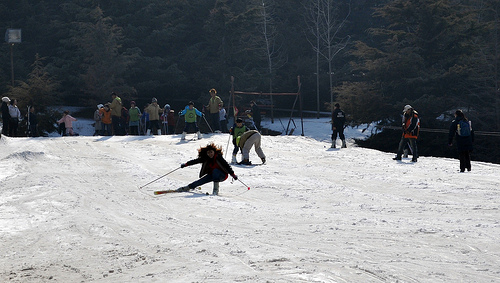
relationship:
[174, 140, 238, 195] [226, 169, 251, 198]
person on skis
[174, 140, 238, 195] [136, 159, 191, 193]
person on skis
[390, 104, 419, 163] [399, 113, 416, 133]
man wearing jacket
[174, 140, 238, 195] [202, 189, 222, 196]
person on ski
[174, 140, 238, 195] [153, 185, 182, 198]
person on ski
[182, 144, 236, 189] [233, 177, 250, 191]
person holding pole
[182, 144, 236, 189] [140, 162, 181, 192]
person holding ski pole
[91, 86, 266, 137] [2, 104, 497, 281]
people standing in snow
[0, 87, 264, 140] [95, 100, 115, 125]
people wearing jacket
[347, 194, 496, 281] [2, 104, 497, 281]
tracks in snow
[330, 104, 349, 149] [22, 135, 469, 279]
man walking in snow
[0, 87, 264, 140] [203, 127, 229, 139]
people walking in snow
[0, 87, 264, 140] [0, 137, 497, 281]
people skiing downhill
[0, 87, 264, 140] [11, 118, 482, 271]
people walking snow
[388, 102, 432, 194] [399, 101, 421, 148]
man wearing coat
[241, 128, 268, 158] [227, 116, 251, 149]
guy equipping child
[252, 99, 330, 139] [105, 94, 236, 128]
fence behind people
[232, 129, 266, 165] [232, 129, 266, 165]
guy front guy